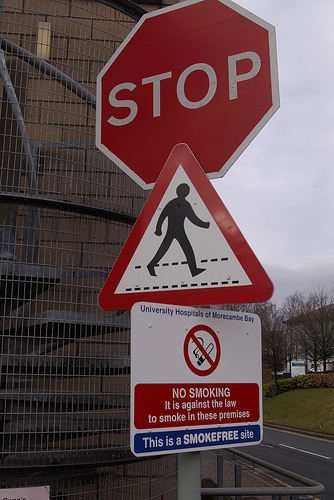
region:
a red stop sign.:
[94, 0, 281, 192]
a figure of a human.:
[146, 182, 211, 278]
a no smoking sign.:
[168, 320, 230, 390]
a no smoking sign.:
[110, 297, 277, 468]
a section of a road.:
[226, 417, 333, 497]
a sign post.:
[178, 444, 212, 499]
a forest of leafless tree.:
[212, 280, 332, 377]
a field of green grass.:
[252, 372, 332, 443]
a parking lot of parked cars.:
[264, 360, 330, 384]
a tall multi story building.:
[0, 1, 176, 463]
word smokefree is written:
[185, 436, 278, 437]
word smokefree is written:
[191, 436, 202, 443]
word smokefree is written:
[196, 434, 209, 441]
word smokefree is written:
[189, 438, 205, 448]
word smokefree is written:
[196, 435, 206, 437]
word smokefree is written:
[185, 440, 199, 448]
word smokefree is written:
[190, 440, 197, 441]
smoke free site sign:
[137, 427, 265, 450]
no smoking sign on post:
[139, 385, 262, 423]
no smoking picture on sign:
[173, 323, 233, 376]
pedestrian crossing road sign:
[142, 176, 217, 286]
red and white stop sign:
[94, 32, 283, 147]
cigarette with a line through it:
[186, 332, 232, 368]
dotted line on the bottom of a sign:
[125, 277, 245, 287]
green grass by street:
[280, 391, 325, 423]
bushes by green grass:
[281, 376, 328, 387]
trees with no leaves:
[299, 302, 331, 369]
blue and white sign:
[127, 427, 261, 472]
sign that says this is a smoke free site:
[124, 426, 253, 463]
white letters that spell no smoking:
[157, 382, 239, 398]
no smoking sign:
[134, 315, 227, 402]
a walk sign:
[119, 161, 205, 304]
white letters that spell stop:
[97, 41, 262, 158]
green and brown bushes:
[264, 364, 328, 417]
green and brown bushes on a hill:
[263, 369, 328, 447]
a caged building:
[13, 361, 120, 496]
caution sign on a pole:
[131, 162, 253, 317]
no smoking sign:
[106, 297, 318, 478]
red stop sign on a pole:
[75, 10, 278, 197]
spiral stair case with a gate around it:
[10, 135, 98, 385]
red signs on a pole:
[84, 26, 282, 247]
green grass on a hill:
[279, 386, 325, 428]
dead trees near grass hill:
[281, 304, 330, 367]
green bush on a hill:
[278, 380, 321, 388]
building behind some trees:
[285, 302, 331, 360]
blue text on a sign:
[134, 430, 273, 456]